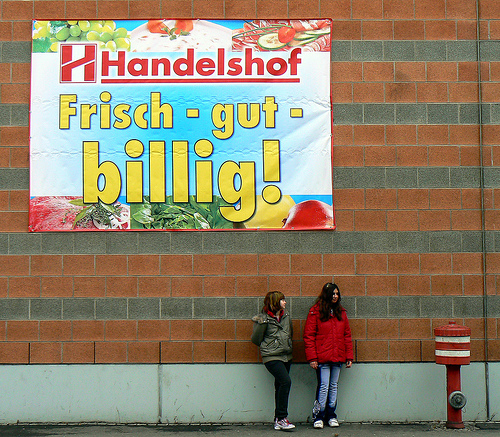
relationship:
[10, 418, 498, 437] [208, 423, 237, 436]
asphalt on ground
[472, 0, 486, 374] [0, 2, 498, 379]
seam in building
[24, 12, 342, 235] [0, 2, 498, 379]
banner on building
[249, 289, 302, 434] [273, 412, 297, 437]
girl has tennis shoe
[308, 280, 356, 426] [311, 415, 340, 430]
girl has tennis shoe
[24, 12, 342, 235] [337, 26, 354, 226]
banner on a wall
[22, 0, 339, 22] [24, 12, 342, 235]
brick behind banner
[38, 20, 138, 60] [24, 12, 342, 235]
grapes on banner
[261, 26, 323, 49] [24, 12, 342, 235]
cucumber on banner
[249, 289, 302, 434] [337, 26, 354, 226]
girl leaning against wall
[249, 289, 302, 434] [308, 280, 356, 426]
girl standing next to girl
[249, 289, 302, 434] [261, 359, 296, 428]
girl wearing black pants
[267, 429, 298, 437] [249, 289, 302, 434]
sidewalk beneath girl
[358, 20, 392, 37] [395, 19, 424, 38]
brick next to brick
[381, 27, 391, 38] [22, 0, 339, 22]
part of a brick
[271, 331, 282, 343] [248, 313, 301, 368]
part of a jacket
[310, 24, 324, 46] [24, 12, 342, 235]
part of a board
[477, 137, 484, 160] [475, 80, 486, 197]
part of a pole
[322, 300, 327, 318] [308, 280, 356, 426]
hair of a lady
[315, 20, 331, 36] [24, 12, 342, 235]
edge of a board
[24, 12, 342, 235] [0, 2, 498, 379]
advertisement on a building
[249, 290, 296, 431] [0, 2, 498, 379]
girl in front of building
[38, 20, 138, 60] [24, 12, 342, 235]
grapes on advertisement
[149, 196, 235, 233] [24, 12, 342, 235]
spinach on advertisement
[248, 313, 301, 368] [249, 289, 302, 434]
jacket on girl